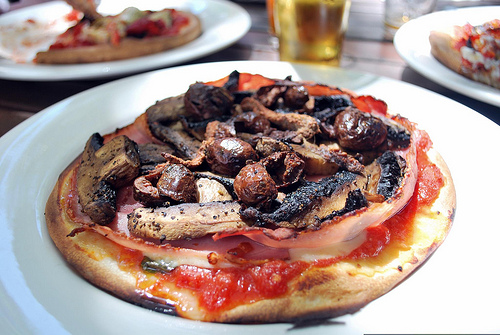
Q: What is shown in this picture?
A: A pizza.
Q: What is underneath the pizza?
A: A white plate.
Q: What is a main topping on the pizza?
A: Mushrooms.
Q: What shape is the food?
A: Round.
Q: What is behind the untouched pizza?
A: A half eaten pizza.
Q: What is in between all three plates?
A: A cup of beer.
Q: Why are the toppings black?
A: Roasted.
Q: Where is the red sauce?
A: On the crust.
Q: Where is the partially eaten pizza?
A: Back left.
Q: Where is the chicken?
A: On the pizza in front.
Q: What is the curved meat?
A: Ham.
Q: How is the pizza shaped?
A: Round.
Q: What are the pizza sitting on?
A: White plates.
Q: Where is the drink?
A: In the middle between the plates.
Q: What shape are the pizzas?
A: Circle.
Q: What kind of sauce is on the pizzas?
A: Tomato.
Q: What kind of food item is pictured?
A: Pizza.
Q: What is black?
A: Mushroom.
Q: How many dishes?
A: Three.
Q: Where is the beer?
A: Middle.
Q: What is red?
A: Sauce.